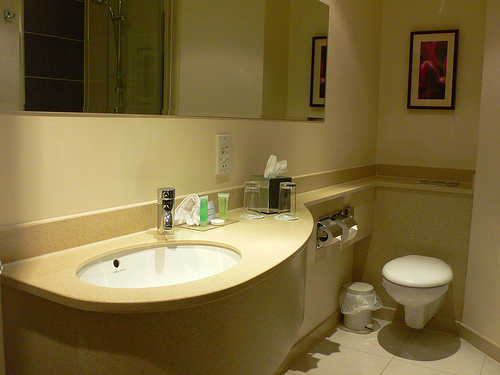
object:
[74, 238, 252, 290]
sink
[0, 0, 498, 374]
bathroom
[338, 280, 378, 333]
trash can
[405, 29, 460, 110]
frame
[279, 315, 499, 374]
floor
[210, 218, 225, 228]
soap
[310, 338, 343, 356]
shadows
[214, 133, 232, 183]
outlet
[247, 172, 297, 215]
box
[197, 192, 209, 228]
shampoo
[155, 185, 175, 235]
faucet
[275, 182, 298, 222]
cup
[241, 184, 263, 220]
cup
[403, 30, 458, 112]
picture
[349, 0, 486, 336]
wall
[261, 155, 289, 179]
tissues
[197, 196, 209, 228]
bottle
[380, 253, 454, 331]
toilet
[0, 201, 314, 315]
counter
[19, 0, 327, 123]
mirror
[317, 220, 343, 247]
paper roll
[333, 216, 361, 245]
paper roll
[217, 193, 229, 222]
hand wash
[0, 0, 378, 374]
wall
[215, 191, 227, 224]
bottle